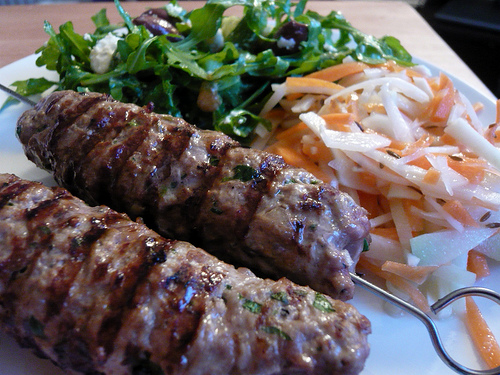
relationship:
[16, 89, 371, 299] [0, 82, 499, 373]
meat on skewer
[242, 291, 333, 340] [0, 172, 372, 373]
seasoning on meat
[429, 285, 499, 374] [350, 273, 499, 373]
handle on skewer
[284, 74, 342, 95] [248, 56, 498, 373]
carrot in salad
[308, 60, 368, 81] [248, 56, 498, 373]
carrot in salad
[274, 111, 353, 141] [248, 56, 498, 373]
carrot in salad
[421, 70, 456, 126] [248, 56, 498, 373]
carrot in salad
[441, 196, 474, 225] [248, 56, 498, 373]
carrot in salad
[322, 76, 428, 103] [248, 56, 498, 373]
cabbage in salad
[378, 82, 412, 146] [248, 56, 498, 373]
cabbage in salad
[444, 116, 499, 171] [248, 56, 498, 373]
cabbage in salad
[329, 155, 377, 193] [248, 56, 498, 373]
cabbage in salad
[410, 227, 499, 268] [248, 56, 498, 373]
cabbage in salad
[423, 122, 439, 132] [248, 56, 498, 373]
fennel seed in salad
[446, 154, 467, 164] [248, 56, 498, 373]
fennel seed in salad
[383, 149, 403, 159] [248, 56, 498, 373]
fennel seed in salad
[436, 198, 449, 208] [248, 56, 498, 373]
fennel seed in salad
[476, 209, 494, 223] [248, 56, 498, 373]
fennel seed in salad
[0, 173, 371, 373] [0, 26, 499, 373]
steak on plate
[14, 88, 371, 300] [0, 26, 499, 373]
steak on plate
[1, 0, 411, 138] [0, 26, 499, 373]
salad on plate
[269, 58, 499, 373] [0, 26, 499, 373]
carrot strips on plate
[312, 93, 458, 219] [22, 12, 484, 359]
strips on plate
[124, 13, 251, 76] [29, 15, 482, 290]
strips on plate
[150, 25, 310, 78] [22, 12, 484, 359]
strips on plate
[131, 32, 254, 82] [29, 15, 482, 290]
strips on plate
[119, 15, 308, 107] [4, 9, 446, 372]
strips on plate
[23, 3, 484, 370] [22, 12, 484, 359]
meal on plate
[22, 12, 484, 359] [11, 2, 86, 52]
plate on table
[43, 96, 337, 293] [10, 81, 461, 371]
lamb on skewer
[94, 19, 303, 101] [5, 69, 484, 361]
greens next to skewers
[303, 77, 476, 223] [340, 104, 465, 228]
carrots in slices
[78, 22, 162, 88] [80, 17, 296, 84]
cheese on greens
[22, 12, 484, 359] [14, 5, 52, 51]
plate on table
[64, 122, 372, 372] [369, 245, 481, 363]
meat on skewer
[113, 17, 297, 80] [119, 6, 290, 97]
pile of leaves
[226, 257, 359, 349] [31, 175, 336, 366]
specks of meat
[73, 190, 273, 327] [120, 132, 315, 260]
mark on meat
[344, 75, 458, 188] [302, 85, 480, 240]
pile of cheese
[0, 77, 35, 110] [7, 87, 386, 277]
skewer sticking out of meat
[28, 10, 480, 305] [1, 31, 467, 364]
food on a plate